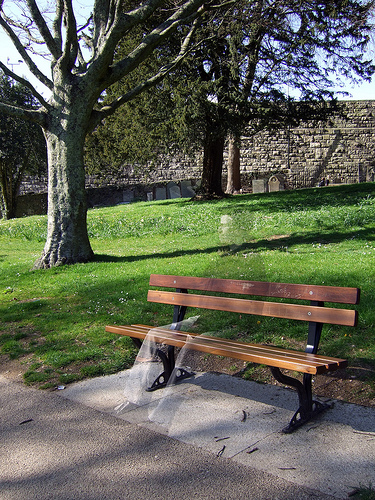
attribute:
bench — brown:
[114, 278, 326, 384]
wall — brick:
[3, 90, 373, 221]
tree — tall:
[0, 2, 220, 273]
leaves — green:
[179, 75, 226, 95]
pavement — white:
[61, 354, 364, 498]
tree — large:
[116, 12, 321, 205]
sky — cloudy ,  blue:
[0, 0, 372, 103]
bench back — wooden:
[144, 270, 367, 328]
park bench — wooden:
[86, 251, 360, 445]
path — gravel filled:
[7, 383, 279, 495]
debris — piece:
[214, 441, 231, 464]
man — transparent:
[113, 202, 270, 450]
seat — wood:
[124, 320, 343, 386]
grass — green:
[1, 181, 371, 386]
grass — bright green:
[1, 179, 373, 406]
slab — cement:
[52, 358, 374, 495]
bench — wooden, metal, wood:
[101, 271, 359, 434]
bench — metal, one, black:
[117, 268, 361, 425]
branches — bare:
[82, 14, 299, 116]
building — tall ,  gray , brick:
[260, 89, 358, 200]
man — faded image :
[125, 212, 267, 424]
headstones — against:
[110, 174, 206, 202]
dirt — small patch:
[205, 229, 296, 253]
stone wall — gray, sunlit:
[15, 99, 373, 194]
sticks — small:
[199, 396, 291, 475]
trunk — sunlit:
[58, 148, 101, 265]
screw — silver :
[305, 310, 314, 316]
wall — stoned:
[0, 99, 372, 216]